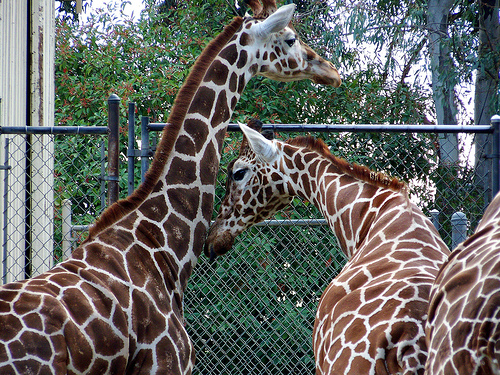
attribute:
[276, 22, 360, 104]
snout — long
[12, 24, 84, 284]
structure — white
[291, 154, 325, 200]
patch — brown, white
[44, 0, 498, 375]
plants — tall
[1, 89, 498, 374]
fence — tall, chainlink, chainlinked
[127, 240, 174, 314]
patch — white, brown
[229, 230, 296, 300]
fence — tall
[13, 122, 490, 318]
fence — metal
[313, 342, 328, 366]
patch — white, brown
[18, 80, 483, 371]
fence — tall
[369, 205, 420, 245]
patch — brown, white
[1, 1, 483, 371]
giraffe — tall